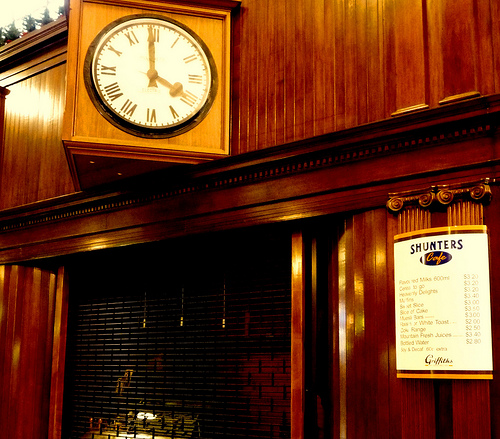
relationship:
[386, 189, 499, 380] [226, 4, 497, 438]
menu on wall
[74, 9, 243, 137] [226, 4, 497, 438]
clock on wall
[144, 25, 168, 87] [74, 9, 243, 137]
hand on clock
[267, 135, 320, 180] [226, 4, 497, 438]
design on wall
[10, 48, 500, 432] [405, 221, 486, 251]
restaurant has name